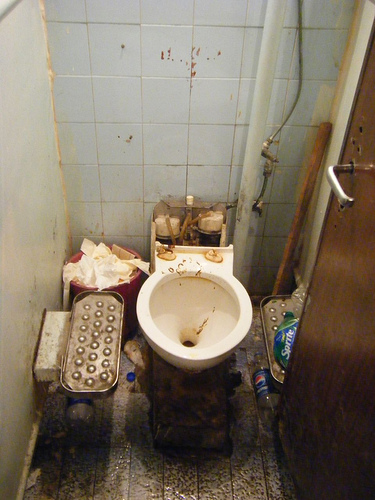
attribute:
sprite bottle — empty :
[268, 304, 310, 376]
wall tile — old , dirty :
[125, 16, 206, 91]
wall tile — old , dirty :
[186, 21, 240, 74]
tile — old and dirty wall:
[124, 60, 196, 120]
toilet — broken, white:
[136, 193, 252, 374]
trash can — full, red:
[69, 242, 144, 336]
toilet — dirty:
[133, 208, 253, 370]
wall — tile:
[37, 4, 356, 300]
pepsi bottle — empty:
[252, 346, 280, 429]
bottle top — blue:
[127, 371, 134, 381]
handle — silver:
[325, 162, 354, 207]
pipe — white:
[230, 1, 289, 285]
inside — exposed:
[152, 203, 221, 245]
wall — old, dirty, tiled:
[52, 14, 274, 182]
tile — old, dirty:
[73, 30, 147, 77]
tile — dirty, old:
[52, 118, 114, 197]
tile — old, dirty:
[85, 119, 155, 169]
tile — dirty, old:
[179, 24, 289, 116]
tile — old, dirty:
[169, 116, 230, 169]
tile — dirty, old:
[130, 154, 197, 196]